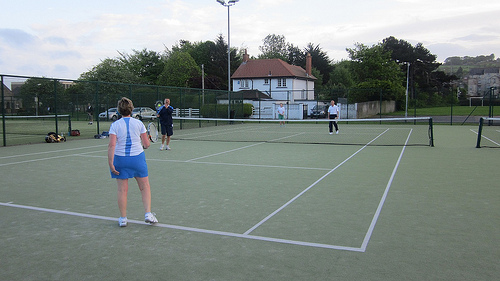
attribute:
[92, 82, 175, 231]
woman — standing, large, wide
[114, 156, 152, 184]
shorts — blue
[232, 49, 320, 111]
house — white, far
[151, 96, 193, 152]
man — wearing, teaching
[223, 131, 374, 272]
court — green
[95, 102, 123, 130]
cars — parked, far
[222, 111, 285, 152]
net — tennis, white, black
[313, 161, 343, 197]
lines — white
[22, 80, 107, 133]
fence — green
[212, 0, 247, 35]
lamp — far, tall